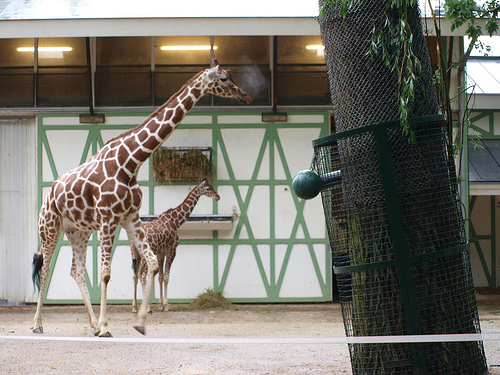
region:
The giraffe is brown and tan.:
[18, 57, 246, 324]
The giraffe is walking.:
[33, 65, 252, 342]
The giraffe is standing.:
[105, 177, 239, 312]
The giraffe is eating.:
[135, 191, 233, 304]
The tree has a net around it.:
[303, 101, 496, 367]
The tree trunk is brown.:
[308, 4, 498, 340]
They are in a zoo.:
[7, 14, 494, 373]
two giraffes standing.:
[23, 62, 264, 350]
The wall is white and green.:
[25, 112, 357, 302]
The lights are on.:
[15, 27, 325, 71]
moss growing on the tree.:
[334, 205, 491, 372]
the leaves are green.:
[330, 2, 498, 151]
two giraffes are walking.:
[21, 58, 255, 342]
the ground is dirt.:
[4, 302, 354, 372]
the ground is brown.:
[2, 289, 353, 372]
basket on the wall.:
[145, 139, 217, 191]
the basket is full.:
[145, 133, 220, 188]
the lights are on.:
[13, 38, 329, 69]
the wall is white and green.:
[27, 97, 341, 311]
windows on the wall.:
[0, 35, 344, 119]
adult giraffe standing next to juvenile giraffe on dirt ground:
[13, 40, 262, 357]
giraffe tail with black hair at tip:
[26, 223, 48, 293]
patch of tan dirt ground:
[182, 316, 318, 373]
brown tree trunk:
[312, 2, 492, 367]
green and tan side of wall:
[40, 116, 329, 307]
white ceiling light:
[12, 44, 76, 61]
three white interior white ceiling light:
[13, 39, 328, 66]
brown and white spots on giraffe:
[76, 172, 123, 201]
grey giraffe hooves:
[91, 314, 157, 345]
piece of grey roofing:
[5, 0, 56, 20]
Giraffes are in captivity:
[1, 28, 492, 363]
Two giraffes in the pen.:
[27, 0, 244, 342]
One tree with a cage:
[290, 1, 490, 366]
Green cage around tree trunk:
[275, 115, 482, 365]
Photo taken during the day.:
[10, 3, 494, 368]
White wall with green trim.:
[20, 104, 337, 308]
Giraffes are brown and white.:
[52, 54, 254, 340]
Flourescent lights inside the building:
[13, 28, 373, 71]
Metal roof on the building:
[432, 0, 492, 196]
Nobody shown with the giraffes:
[5, 9, 490, 371]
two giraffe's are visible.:
[21, 55, 256, 342]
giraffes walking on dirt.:
[27, 57, 256, 338]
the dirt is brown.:
[2, 292, 356, 370]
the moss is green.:
[333, 193, 483, 363]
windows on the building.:
[2, 25, 350, 123]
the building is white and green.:
[1, 96, 348, 311]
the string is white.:
[1, 324, 498, 351]